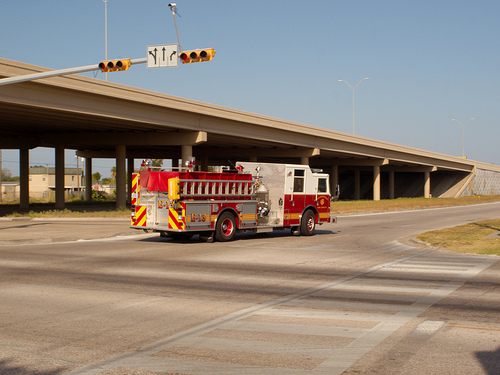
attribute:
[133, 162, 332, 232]
truck — red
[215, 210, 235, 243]
tire — rear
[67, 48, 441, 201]
bridge — large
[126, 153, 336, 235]
firetruck — red , white 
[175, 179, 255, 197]
ladder — gray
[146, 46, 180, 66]
signs — white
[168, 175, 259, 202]
ladder — detachable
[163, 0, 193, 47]
camera — white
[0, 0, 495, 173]
sky — blue, clear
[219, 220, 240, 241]
rim — red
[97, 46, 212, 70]
traffic light — horizontal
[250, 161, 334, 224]
cab — white